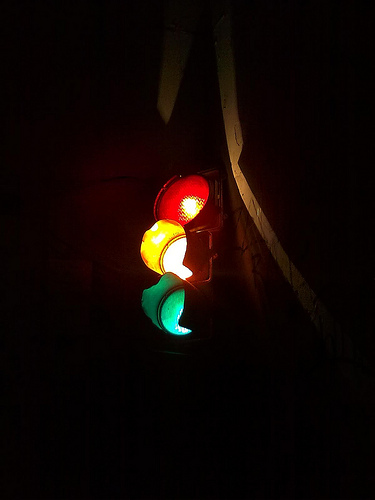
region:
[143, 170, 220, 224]
red stop light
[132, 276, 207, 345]
green light on pole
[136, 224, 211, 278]
yellow light on the pole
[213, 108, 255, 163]
white strip on the pole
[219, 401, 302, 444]
black surrounding the picture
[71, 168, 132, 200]
red near the lights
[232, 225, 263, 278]
pole the lights are hanging on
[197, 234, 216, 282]
part of the yellow light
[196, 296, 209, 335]
part of the green light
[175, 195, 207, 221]
bulb in the red light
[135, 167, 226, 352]
decorative indoor light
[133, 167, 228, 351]
fake traffic light interior lamp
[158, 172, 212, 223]
red circle of a traffic light lamp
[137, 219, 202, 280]
yellow circle of a traffic light lamp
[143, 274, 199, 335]
green circle of a traffic light lamp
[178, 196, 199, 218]
plastic bulb shield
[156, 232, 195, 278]
plastic round shield protecting lamp bulb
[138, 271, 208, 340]
round reflective light shield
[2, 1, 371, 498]
illuminated traffic light lamp surrounded by darkness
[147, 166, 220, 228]
a red traffic light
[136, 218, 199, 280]
a yellow traffic light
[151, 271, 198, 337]
a green traffic light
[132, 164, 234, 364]
a bank of traffic lights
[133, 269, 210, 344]
the cover of the traffic light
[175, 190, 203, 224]
the center of the red light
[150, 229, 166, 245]
light reflecting off the cover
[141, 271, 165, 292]
a bent section of the cover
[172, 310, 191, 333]
the center of the green light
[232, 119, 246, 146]
a section of chipped paint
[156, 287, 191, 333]
Green light is lit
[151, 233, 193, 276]
Orange light is lit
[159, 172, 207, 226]
Red light is lit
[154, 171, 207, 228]
Red light on traffic light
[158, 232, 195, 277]
Orange light on traffic light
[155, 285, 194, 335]
Green light on traffic light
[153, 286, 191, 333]
Green light below orange light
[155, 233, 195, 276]
Orange light above green light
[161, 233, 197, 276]
Orange light below red light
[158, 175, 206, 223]
Red light above orange light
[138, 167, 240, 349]
A traffic light hanging in the dark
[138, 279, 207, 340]
A green light on a traffic light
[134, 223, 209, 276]
The yellow light on a traffic light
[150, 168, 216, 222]
The red light on a traffic light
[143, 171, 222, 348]
A traffic light with all lights lit up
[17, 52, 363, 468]
A traffic light in the dark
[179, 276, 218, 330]
The metal sides by the light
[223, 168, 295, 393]
The pole supporting the traffic light partially lit up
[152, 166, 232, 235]
A square portion of a traffic light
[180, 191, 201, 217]
The reflection of light on the red light